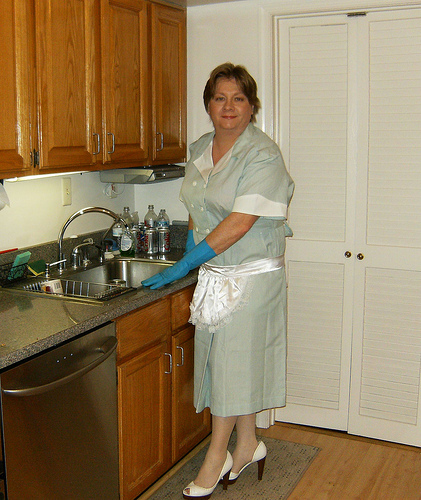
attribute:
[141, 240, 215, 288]
glove — blue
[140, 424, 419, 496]
floor — wooden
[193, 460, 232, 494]
shoe — white, high heeled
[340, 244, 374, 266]
knobs — gold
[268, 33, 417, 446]
doors — white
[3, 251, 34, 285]
sponge — green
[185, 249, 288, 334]
apron — white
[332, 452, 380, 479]
wood flooring — brown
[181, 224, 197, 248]
rubber glove — blue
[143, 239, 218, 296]
rubber glove — blue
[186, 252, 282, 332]
apron — small, white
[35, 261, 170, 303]
sink — stainless steel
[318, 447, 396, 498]
floor — light brown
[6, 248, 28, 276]
sponge — light blue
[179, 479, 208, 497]
dress shoe — white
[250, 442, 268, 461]
dress shoe — white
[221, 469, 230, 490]
heel — brown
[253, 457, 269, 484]
heel — brown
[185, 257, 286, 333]
apron — white, satin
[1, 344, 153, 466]
dishwasher — stainless steel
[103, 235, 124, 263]
scrub brush — blue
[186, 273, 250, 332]
trim — ruffled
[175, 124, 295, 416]
dress — blue, white